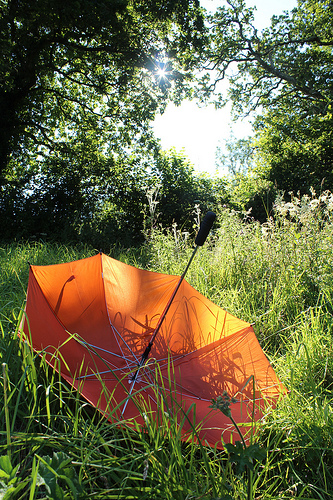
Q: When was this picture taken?
A: Daytime.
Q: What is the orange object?
A: Umbrella.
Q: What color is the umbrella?
A: Orange.